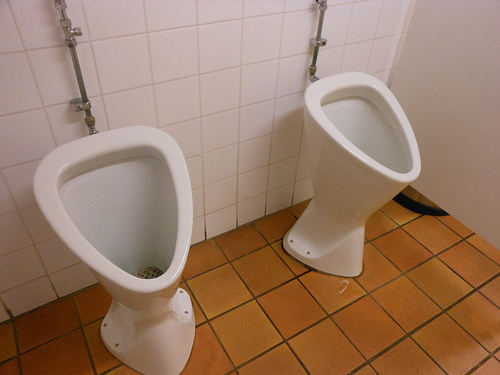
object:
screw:
[103, 322, 108, 328]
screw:
[114, 342, 121, 348]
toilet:
[281, 68, 423, 279]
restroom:
[0, 0, 499, 374]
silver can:
[392, 186, 450, 218]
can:
[393, 193, 448, 216]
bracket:
[70, 95, 91, 112]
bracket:
[58, 18, 83, 48]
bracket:
[310, 36, 328, 48]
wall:
[0, 0, 498, 330]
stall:
[0, 0, 499, 375]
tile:
[213, 225, 268, 261]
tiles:
[0, 0, 414, 325]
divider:
[386, 0, 499, 250]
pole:
[54, 0, 101, 137]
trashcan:
[393, 189, 448, 217]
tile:
[183, 240, 226, 279]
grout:
[368, 276, 446, 335]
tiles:
[0, 289, 206, 374]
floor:
[0, 195, 499, 373]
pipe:
[54, 1, 101, 136]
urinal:
[30, 123, 210, 373]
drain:
[133, 266, 163, 279]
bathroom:
[0, 0, 499, 375]